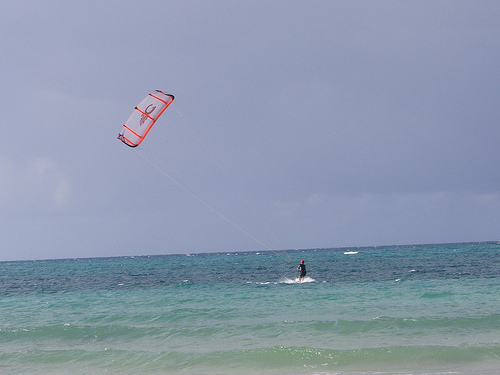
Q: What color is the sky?
A: Blue.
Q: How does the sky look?
A: Clear.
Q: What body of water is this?
A: An ocean.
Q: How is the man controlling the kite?
A: He's holding string attached to kite.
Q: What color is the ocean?
A: Green.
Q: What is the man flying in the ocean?
A: Kite.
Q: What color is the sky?
A: Blue.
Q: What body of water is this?
A: Ocean.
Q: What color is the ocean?
A: Blue.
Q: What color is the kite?
A: Grey and orange.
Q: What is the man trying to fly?
A: A kite.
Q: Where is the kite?
A: In the sky.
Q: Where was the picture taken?
A: Ocean.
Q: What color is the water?
A: Blue and green.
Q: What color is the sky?
A: Grey and hazy.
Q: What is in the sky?
A: A kite.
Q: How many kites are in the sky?
A: One.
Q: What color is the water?
A: Blue.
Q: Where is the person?
A: In the water.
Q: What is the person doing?
A: Skiing.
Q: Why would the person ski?
A: For fun.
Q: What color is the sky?
A: Clear and blue.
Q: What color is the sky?
A: Blue.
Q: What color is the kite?
A: White and red.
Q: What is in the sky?
A: A kite.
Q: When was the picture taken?
A: Daytime.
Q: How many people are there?
A: One.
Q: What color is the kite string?
A: White.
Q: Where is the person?
A: In the water.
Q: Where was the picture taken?
A: Water.